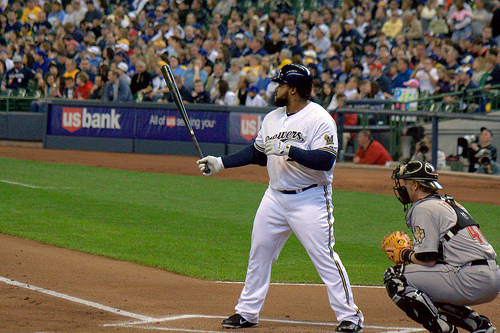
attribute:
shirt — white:
[253, 101, 338, 182]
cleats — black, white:
[225, 312, 257, 327]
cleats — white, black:
[337, 319, 361, 331]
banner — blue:
[46, 104, 260, 137]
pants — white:
[231, 181, 368, 328]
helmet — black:
[272, 63, 312, 96]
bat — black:
[125, 36, 230, 194]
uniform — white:
[234, 100, 364, 327]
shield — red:
[60, 106, 79, 131]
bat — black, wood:
[157, 57, 212, 180]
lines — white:
[4, 274, 134, 331]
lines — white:
[100, 320, 194, 329]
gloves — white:
[193, 134, 290, 176]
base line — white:
[53, 292, 120, 314]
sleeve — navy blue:
[288, 144, 335, 172]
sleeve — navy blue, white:
[221, 141, 261, 168]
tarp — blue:
[44, 100, 279, 144]